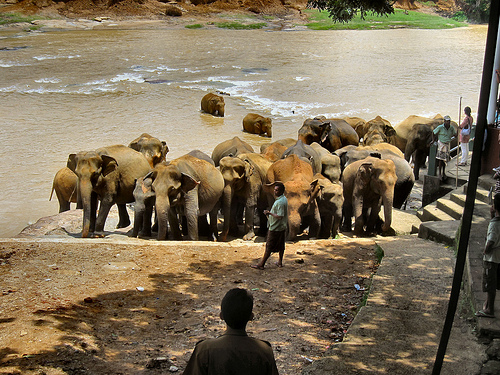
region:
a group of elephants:
[39, 46, 464, 292]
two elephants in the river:
[173, 63, 276, 138]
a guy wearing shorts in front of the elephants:
[176, 119, 328, 277]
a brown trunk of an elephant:
[65, 172, 102, 238]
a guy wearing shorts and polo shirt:
[239, 169, 299, 278]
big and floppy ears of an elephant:
[57, 151, 117, 178]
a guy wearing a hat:
[424, 107, 455, 174]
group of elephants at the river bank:
[26, 95, 190, 237]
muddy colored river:
[324, 42, 444, 90]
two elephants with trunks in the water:
[168, 72, 280, 139]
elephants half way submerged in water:
[186, 87, 274, 141]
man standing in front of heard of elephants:
[252, 176, 297, 274]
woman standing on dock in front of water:
[454, 101, 474, 176]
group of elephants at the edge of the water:
[47, 107, 469, 236]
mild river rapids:
[11, 53, 305, 117]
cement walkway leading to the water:
[335, 235, 480, 368]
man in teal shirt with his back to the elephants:
[427, 103, 456, 172]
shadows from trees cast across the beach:
[16, 244, 432, 373]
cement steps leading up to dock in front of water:
[415, 168, 497, 217]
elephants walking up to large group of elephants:
[199, 86, 272, 136]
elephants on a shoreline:
[9, 10, 494, 352]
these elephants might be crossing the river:
[108, 38, 333, 168]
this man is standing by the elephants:
[72, 95, 339, 250]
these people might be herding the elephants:
[337, 77, 483, 216]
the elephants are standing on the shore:
[50, 74, 455, 294]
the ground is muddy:
[17, 202, 435, 365]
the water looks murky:
[12, 25, 436, 145]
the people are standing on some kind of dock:
[418, 83, 499, 248]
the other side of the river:
[3, 2, 468, 62]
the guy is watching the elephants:
[106, 140, 371, 363]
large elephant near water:
[67, 145, 133, 215]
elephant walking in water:
[200, 90, 225, 120]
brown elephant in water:
[226, 102, 281, 137]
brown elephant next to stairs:
[336, 135, 402, 230]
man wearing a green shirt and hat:
[430, 110, 455, 160]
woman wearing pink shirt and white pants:
[455, 90, 470, 150]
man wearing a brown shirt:
[215, 265, 285, 370]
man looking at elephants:
[205, 280, 295, 370]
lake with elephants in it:
[40, 35, 165, 115]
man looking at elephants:
[481, 197, 496, 301]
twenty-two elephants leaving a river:
[45, 95, 455, 236]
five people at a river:
[186, 101, 493, 368]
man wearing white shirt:
[262, 180, 292, 270]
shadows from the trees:
[24, 273, 186, 365]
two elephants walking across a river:
[195, 85, 275, 135]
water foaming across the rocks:
[12, 58, 172, 104]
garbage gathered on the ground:
[295, 270, 370, 363]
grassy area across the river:
[296, 10, 462, 28]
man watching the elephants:
[178, 287, 283, 372]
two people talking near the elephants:
[434, 106, 471, 173]